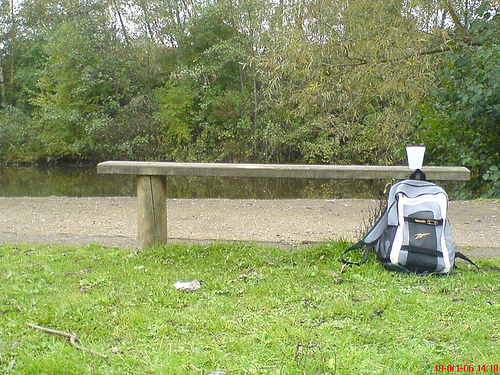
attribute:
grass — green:
[10, 246, 493, 372]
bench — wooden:
[95, 153, 473, 256]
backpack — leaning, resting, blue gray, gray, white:
[340, 169, 476, 277]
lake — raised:
[4, 155, 487, 201]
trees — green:
[5, 7, 498, 172]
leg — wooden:
[133, 174, 172, 261]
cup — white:
[406, 145, 430, 172]